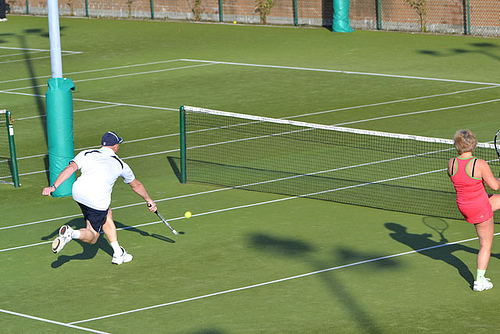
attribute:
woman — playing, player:
[433, 123, 491, 287]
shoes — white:
[473, 278, 492, 295]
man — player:
[42, 111, 152, 261]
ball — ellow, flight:
[181, 203, 194, 228]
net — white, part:
[212, 120, 314, 171]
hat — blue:
[88, 127, 123, 146]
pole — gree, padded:
[167, 111, 186, 189]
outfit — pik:
[449, 163, 478, 217]